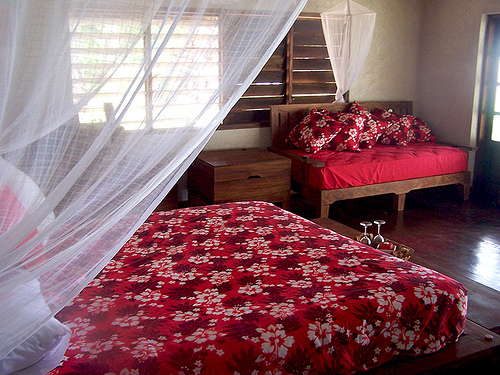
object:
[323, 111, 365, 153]
pillows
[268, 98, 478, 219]
couch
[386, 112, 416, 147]
cushions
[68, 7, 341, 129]
blinds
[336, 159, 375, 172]
sheet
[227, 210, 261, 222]
flowers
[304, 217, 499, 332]
bench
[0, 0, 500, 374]
room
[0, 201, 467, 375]
matress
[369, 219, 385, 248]
wine glasses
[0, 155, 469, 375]
bed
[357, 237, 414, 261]
basket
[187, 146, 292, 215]
dresser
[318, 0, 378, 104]
shear cover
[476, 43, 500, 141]
light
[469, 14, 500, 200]
door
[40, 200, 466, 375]
bed spread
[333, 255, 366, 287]
floral print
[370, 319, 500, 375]
bed frame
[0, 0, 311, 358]
net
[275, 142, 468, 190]
bed sheet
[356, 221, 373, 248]
wineglass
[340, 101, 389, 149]
pillow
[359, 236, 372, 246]
down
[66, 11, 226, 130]
curtain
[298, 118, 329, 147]
flower pattern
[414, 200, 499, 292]
floor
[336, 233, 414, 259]
tray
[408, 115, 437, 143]
cushion